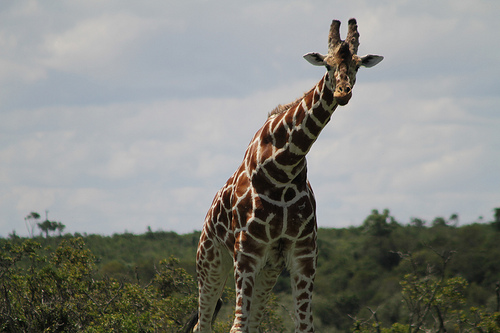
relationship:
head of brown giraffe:
[302, 9, 391, 112] [179, 18, 382, 333]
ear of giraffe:
[356, 45, 395, 82] [118, 19, 426, 289]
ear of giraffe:
[302, 39, 334, 97] [163, 12, 420, 332]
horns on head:
[328, 18, 360, 61] [311, 17, 380, 107]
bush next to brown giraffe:
[0, 224, 196, 331] [179, 18, 382, 333]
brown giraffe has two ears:
[179, 18, 382, 333] [301, 52, 383, 67]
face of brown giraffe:
[312, 50, 377, 112] [179, 18, 382, 333]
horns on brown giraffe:
[323, 16, 366, 63] [179, 18, 382, 333]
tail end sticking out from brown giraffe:
[185, 310, 197, 332] [179, 18, 382, 333]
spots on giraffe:
[247, 164, 316, 245] [84, 23, 451, 308]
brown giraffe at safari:
[179, 18, 382, 333] [4, 5, 475, 331]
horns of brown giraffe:
[328, 18, 360, 61] [179, 18, 382, 333]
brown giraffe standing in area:
[179, 18, 382, 333] [0, 222, 475, 331]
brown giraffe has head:
[179, 18, 382, 333] [297, 4, 387, 109]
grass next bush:
[309, 213, 488, 295] [0, 210, 197, 333]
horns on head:
[328, 18, 360, 61] [297, 12, 391, 119]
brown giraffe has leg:
[179, 18, 382, 333] [228, 257, 259, 331]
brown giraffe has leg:
[179, 18, 382, 333] [288, 242, 320, 331]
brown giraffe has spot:
[179, 18, 382, 333] [280, 192, 316, 241]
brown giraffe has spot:
[179, 18, 382, 333] [233, 253, 258, 277]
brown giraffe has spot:
[179, 18, 382, 333] [232, 170, 252, 199]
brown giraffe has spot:
[179, 18, 382, 333] [286, 101, 311, 135]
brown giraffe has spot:
[179, 18, 382, 333] [228, 168, 253, 200]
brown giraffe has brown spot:
[179, 18, 382, 333] [255, 123, 276, 160]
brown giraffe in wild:
[179, 18, 382, 333] [2, 215, 494, 331]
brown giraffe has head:
[179, 18, 382, 333] [305, 16, 382, 105]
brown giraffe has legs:
[179, 18, 382, 333] [188, 264, 322, 331]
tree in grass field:
[16, 202, 70, 239] [1, 228, 499, 331]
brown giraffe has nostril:
[179, 18, 382, 333] [345, 85, 352, 95]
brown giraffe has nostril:
[179, 18, 382, 333] [334, 83, 341, 91]